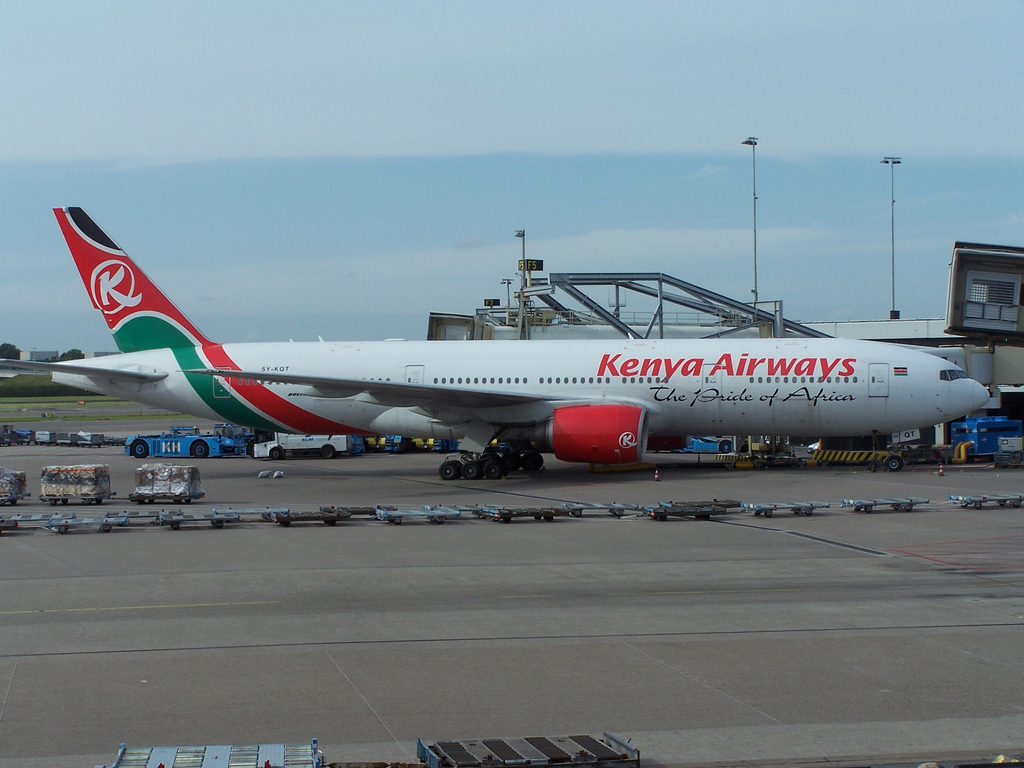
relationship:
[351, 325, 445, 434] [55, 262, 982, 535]
sidedoor on airplane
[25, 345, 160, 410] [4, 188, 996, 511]
wing on plane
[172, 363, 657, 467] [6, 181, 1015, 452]
wing on plane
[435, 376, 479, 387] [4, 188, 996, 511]
window on plane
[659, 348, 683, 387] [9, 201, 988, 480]
letter on plane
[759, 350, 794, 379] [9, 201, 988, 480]
letter on plane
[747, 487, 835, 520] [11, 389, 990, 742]
trailer on tarmac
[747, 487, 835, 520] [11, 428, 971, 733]
trailer on tarmac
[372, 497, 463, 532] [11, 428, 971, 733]
trailer on tarmac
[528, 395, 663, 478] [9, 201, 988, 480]
engine on a plane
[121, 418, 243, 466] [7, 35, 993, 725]
tractor at the airport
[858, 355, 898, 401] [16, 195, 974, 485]
door on a airplane